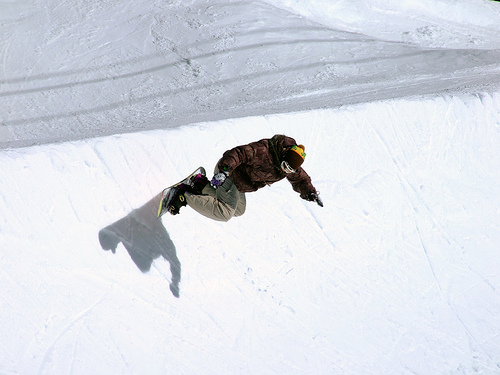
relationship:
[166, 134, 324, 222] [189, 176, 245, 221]
man wearing pants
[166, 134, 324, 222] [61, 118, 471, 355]
man snowboarding down slope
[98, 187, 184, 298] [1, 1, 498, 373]
shadow on ground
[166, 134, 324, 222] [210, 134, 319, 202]
man wearing coat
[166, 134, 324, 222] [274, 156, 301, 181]
man wearing goggles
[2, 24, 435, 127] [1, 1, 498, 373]
lines on ground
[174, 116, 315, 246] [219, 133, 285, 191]
man wearing coat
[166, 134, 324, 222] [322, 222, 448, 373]
man on snow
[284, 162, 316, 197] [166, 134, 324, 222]
arm on man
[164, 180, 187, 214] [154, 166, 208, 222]
feet touching board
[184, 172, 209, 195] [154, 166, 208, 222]
feet touching board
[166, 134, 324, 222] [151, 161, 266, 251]
man wearing pants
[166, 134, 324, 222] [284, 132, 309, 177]
man wearing cap